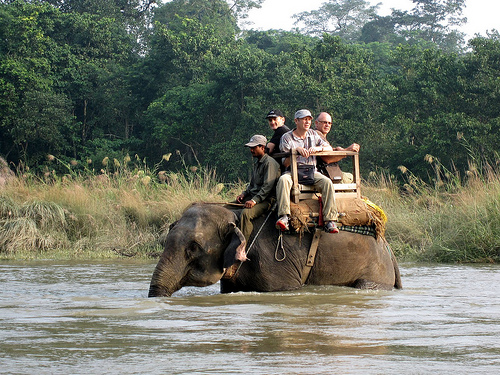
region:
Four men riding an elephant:
[183, 104, 348, 294]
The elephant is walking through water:
[137, 187, 414, 327]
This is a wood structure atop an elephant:
[280, 142, 365, 203]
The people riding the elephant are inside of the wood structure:
[282, 123, 364, 199]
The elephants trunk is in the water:
[139, 209, 232, 329]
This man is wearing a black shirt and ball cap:
[265, 108, 290, 148]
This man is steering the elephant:
[241, 134, 267, 233]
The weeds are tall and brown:
[26, 153, 140, 245]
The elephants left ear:
[219, 217, 250, 272]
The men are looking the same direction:
[258, 99, 335, 139]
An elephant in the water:
[117, 185, 409, 293]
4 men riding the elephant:
[227, 88, 377, 244]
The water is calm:
[17, 270, 484, 362]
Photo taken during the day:
[5, 15, 480, 366]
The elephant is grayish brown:
[134, 203, 421, 305]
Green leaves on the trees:
[0, 12, 487, 204]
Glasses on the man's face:
[315, 120, 344, 131]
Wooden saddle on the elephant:
[245, 135, 392, 252]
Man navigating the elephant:
[234, 135, 277, 249]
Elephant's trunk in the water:
[132, 253, 199, 310]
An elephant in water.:
[145, 98, 417, 325]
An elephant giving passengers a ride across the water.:
[126, 97, 404, 306]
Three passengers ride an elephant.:
[148, 108, 400, 322]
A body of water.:
[22, 304, 307, 370]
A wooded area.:
[57, 51, 222, 162]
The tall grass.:
[38, 172, 132, 234]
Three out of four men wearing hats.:
[231, 103, 371, 170]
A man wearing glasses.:
[314, 108, 336, 148]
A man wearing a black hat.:
[263, 106, 288, 148]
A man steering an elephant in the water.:
[140, 132, 275, 318]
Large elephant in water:
[137, 195, 405, 300]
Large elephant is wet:
[140, 198, 402, 292]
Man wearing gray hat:
[272, 108, 342, 235]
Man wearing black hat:
[261, 106, 290, 147]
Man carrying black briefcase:
[272, 108, 340, 233]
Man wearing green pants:
[223, 131, 285, 264]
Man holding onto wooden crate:
[311, 108, 363, 183]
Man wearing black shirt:
[264, 106, 289, 151]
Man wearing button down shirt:
[222, 133, 280, 263]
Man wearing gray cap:
[212, 131, 279, 267]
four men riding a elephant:
[142, 80, 387, 351]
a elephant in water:
[121, 171, 451, 321]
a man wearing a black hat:
[260, 97, 295, 138]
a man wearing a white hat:
[295, 105, 310, 140]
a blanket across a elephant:
[265, 191, 382, 237]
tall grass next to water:
[392, 158, 490, 282]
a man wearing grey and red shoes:
[314, 215, 343, 237]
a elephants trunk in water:
[131, 203, 238, 320]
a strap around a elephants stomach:
[293, 224, 330, 288]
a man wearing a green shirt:
[244, 150, 276, 195]